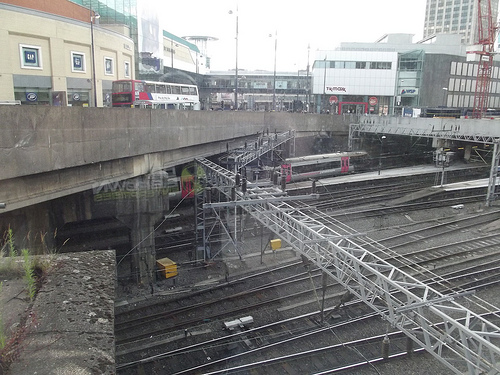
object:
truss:
[194, 154, 500, 375]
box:
[156, 257, 179, 280]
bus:
[111, 79, 202, 112]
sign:
[25, 51, 36, 63]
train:
[167, 151, 373, 202]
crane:
[467, 2, 499, 118]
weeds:
[0, 220, 73, 302]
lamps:
[226, 0, 240, 109]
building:
[441, 35, 499, 111]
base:
[4, 171, 167, 258]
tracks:
[82, 203, 499, 374]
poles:
[235, 0, 239, 109]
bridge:
[0, 91, 280, 183]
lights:
[93, 12, 100, 19]